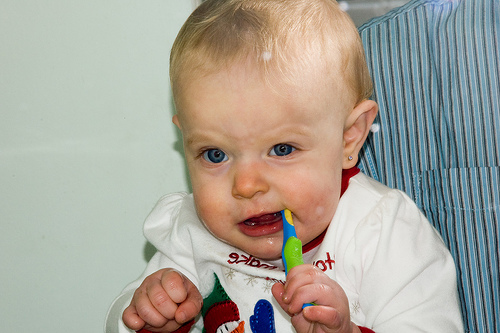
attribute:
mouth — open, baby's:
[234, 207, 291, 237]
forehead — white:
[176, 76, 303, 131]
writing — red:
[225, 249, 285, 280]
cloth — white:
[328, 207, 432, 329]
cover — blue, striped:
[349, 9, 494, 332]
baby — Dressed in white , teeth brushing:
[105, 0, 463, 331]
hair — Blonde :
[168, 0, 375, 102]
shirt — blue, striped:
[352, 0, 499, 331]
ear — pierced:
[341, 96, 379, 172]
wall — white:
[1, 0, 191, 331]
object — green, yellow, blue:
[280, 209, 315, 309]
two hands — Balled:
[121, 261, 352, 331]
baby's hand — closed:
[122, 265, 204, 328]